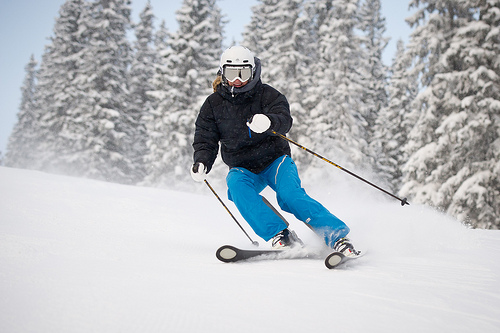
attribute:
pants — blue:
[229, 156, 345, 239]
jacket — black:
[170, 90, 296, 164]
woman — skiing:
[206, 47, 273, 115]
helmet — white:
[215, 42, 258, 73]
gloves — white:
[173, 112, 274, 192]